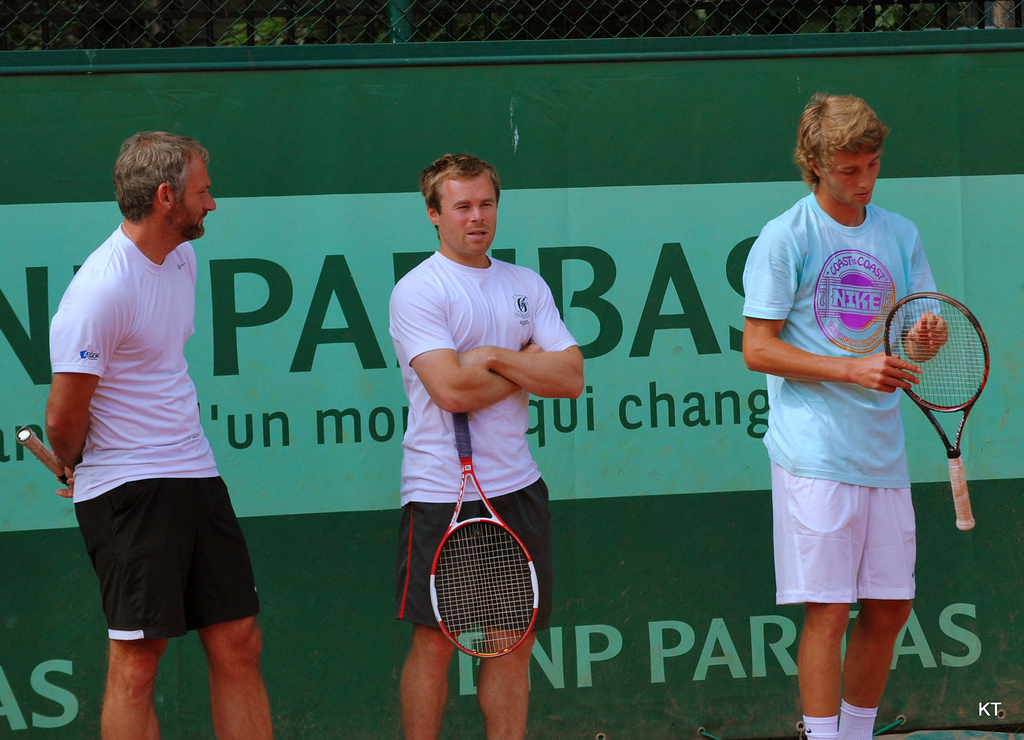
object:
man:
[387, 154, 585, 740]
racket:
[430, 412, 538, 658]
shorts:
[74, 475, 259, 641]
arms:
[389, 269, 583, 413]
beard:
[165, 195, 208, 240]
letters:
[209, 254, 387, 376]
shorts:
[770, 459, 916, 605]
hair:
[792, 92, 891, 195]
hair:
[113, 131, 211, 225]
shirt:
[742, 190, 941, 489]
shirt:
[388, 250, 578, 507]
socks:
[803, 714, 840, 739]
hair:
[419, 153, 500, 240]